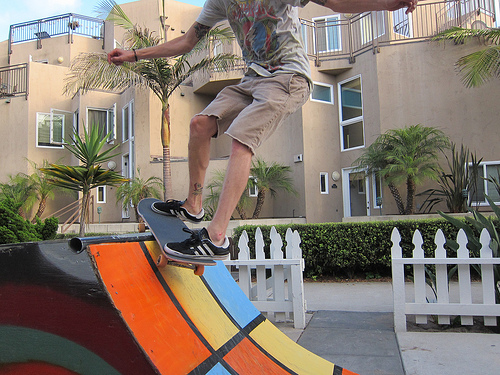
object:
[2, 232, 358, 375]
jump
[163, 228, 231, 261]
sneakers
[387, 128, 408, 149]
leaf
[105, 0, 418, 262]
man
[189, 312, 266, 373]
line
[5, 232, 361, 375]
ramp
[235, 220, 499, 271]
leaves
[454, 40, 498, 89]
green leaf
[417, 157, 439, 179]
green leaf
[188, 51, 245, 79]
green leaf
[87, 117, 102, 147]
green leaf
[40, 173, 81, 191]
green leaf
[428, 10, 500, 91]
tree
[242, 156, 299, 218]
tree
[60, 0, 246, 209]
tree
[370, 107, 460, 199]
leaf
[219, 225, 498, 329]
fence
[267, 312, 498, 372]
sidewalk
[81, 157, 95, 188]
leaf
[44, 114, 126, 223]
tree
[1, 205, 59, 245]
tree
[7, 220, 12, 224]
leaf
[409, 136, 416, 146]
leaf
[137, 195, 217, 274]
skateboard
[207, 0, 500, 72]
balcony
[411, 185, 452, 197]
leaf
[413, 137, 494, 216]
tree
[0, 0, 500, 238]
building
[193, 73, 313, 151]
shorts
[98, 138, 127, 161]
leaf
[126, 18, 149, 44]
leaf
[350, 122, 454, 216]
tree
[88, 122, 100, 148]
leaf